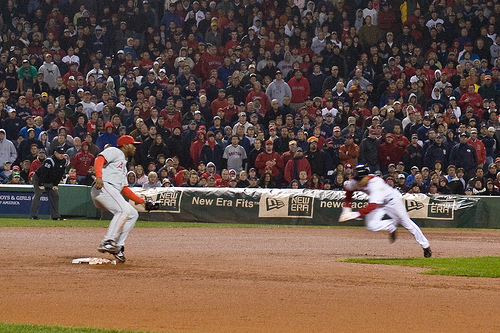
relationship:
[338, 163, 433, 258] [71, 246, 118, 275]
baseball player running to base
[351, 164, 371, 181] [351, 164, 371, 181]
helmet on helmet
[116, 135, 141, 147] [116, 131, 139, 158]
cap on man's head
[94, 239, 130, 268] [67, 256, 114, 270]
foot near base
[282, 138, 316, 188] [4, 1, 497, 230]
person in stands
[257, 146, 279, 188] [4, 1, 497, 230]
person in stands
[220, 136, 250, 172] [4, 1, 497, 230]
person in stands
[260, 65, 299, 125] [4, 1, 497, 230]
person in stands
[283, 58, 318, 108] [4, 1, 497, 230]
person in stands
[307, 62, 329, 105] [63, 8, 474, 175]
person in stands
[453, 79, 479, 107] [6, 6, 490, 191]
person in stands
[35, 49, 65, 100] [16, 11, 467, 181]
person in stands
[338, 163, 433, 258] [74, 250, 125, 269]
baseball player running to base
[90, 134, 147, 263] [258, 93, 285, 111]
baseball infielder trying to catch ball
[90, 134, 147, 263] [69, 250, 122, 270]
baseball infielder trying to tag base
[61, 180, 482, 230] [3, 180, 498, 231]
advertising banner on wall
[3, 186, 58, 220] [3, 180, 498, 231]
advertising banner on wall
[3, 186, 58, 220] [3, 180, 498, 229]
advertising banner behind umpire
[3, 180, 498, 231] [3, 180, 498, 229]
wall behind umpire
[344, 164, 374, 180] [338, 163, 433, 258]
helmet on baseball player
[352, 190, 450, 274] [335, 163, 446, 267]
pants on baseball player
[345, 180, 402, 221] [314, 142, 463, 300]
white jersey on baseball player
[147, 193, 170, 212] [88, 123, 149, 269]
glove on baseball infielder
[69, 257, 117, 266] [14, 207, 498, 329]
base on baseball field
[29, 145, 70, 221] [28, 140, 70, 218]
dark clothing in dark clothing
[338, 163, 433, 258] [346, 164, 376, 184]
baseball player wearing helmet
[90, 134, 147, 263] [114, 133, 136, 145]
baseball infielder wearing hat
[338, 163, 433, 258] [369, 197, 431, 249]
baseball player wearing pants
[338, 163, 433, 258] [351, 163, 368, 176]
baseball player wearing helmet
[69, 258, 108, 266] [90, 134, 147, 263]
base behind baseball infielder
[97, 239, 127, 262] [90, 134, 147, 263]
foot of baseball infielder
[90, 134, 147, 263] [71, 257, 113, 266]
baseball infielder near base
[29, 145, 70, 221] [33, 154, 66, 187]
dark clothing wearing jacket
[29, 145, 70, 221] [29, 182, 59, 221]
dark clothing wearing pants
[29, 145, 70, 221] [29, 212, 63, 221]
dark clothing wearing shoes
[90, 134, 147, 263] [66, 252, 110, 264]
baseball infielder on base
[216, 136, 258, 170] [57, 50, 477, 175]
person in the stands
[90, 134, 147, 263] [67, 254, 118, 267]
baseball infielder on base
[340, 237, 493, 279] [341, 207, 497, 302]
grass of infield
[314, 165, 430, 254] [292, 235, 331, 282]
baseball player diving towards second base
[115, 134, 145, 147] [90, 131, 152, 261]
cap on baseball infielder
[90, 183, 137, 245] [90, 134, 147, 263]
pants worn by baseball infielder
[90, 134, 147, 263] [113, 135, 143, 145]
baseball infielder in hat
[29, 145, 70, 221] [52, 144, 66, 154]
dark clothing wearing hat